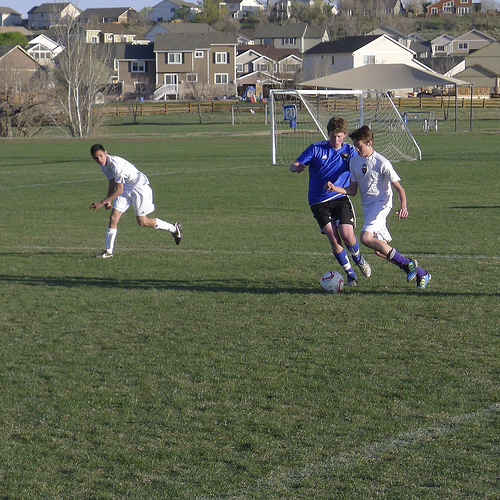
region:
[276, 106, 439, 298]
Two boys play soccer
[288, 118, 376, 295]
A boy in a blue uniform kicks the ball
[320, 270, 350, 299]
A red and white soccer ball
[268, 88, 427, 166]
A white goal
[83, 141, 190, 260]
A boy in a white uniform runs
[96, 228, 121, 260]
White knee socks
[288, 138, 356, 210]
Boy wears blue t-shirt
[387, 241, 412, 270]
Purple soccer socks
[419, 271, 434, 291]
A blue soccer cleat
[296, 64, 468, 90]
A tan awning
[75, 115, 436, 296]
three soccer players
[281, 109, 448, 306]
soccer players running for soccer ball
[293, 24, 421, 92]
white house with black roof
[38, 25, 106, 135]
tree with no leaves next to field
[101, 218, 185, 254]
white socks of soccer player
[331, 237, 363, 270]
blue socks of soccer player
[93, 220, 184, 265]
black cleats of soccer player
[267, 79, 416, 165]
white netting of soccer goal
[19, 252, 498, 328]
shadows on soccer field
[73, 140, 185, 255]
soccer player running by himself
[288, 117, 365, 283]
soccer player with blue jersey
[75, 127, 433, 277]
two soccer players with white jerseys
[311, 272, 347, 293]
white soccer ball being chased by two players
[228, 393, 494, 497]
faded white line on field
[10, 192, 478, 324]
shadows on the soccer field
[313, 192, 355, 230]
black shorts of player with blue jersey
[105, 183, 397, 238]
white shorts of two soccer players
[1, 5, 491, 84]
houses behind soccer field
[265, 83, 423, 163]
white goal on soccer field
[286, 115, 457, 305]
Two opponents aim feet soccer ball.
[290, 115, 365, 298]
Blue uniformed player closest ball.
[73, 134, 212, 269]
Soccer player all in white.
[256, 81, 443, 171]
Soccer goal white mesh cage.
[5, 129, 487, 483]
Soccer field green grass white lines.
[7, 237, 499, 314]
All player's shadows on grass.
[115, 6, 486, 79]
Family homes skirt play field.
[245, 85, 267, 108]
Children' s slide playground behind house.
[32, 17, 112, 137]
Leafless birch tree grows.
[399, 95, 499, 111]
Wooden fence around play field.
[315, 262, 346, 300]
soccer ball on greass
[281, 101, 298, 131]
blue sign with black "21" on white background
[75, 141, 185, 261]
soccer player in white on the left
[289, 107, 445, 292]
two soccer players on opposing teams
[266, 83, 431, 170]
soccer goal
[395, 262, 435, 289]
shoes of the player on the right wearing white uniform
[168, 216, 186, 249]
left shoe of player on left wearing white uniform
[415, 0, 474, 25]
orange-red house in upper right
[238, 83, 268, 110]
playground equipment in upper center of picture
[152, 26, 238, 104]
tan house with 6 visible windows in upper center